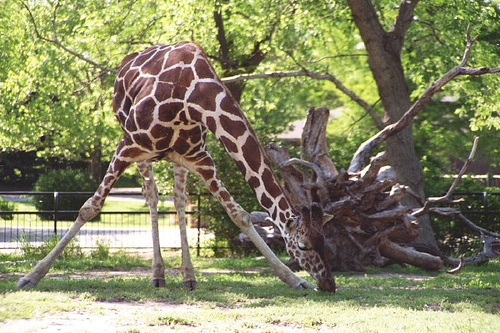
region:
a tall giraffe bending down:
[16, 38, 356, 309]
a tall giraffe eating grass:
[18, 35, 338, 299]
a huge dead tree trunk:
[255, 64, 480, 280]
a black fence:
[1, 169, 496, 264]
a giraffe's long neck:
[181, 73, 293, 214]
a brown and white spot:
[151, 95, 186, 127]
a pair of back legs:
[143, 145, 199, 302]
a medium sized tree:
[266, 3, 471, 258]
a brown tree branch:
[214, 59, 394, 135]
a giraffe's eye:
[292, 234, 310, 254]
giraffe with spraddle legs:
[20, 36, 342, 293]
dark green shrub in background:
[31, 170, 105, 221]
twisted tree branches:
[270, 92, 490, 277]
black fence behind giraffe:
[0, 187, 279, 254]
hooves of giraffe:
[13, 270, 308, 303]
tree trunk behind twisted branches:
[373, 78, 452, 262]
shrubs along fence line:
[206, 143, 499, 248]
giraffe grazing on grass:
[27, 36, 354, 298]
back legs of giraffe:
[132, 161, 209, 285]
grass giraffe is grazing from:
[11, 268, 486, 330]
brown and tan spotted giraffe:
[109, 43, 324, 307]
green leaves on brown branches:
[18, 17, 73, 69]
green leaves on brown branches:
[8, 59, 55, 99]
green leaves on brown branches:
[298, 64, 340, 94]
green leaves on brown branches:
[415, 47, 463, 99]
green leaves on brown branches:
[265, 11, 332, 66]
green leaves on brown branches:
[348, 17, 400, 52]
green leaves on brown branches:
[85, 11, 153, 31]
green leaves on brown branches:
[135, 3, 237, 25]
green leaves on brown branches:
[15, 77, 70, 121]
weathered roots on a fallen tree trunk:
[288, 98, 452, 268]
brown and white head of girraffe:
[264, 194, 347, 302]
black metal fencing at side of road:
[0, 181, 219, 261]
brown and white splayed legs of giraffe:
[11, 128, 323, 300]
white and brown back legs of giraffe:
[120, 132, 214, 290]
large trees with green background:
[344, 0, 467, 269]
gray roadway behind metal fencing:
[0, 209, 195, 253]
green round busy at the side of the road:
[24, 160, 115, 226]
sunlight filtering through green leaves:
[24, 7, 354, 69]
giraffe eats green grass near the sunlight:
[6, 28, 352, 300]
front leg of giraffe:
[23, 143, 142, 278]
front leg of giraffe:
[187, 159, 309, 289]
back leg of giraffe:
[145, 168, 162, 290]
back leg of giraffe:
[172, 169, 196, 288]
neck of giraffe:
[202, 91, 294, 228]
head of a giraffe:
[284, 228, 337, 293]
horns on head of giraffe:
[298, 211, 325, 224]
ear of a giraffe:
[263, 215, 282, 231]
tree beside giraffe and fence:
[332, 5, 457, 255]